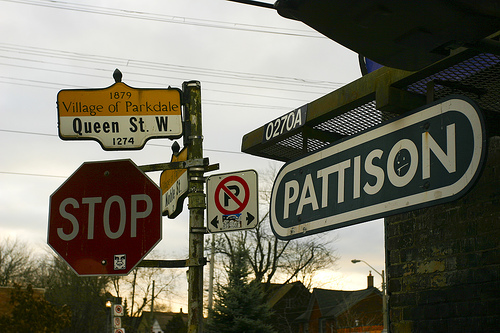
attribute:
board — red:
[44, 157, 164, 278]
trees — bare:
[206, 232, 338, 281]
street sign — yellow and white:
[55, 80, 185, 150]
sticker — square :
[110, 252, 129, 270]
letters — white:
[275, 120, 466, 222]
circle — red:
[215, 176, 249, 214]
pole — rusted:
[176, 84, 211, 331]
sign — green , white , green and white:
[264, 98, 483, 244]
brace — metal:
[138, 258, 208, 268]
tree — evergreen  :
[203, 228, 323, 330]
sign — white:
[202, 172, 267, 234]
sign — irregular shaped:
[55, 66, 182, 152]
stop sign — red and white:
[44, 162, 165, 283]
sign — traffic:
[198, 168, 265, 237]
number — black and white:
[250, 99, 310, 146]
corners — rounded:
[452, 148, 484, 198]